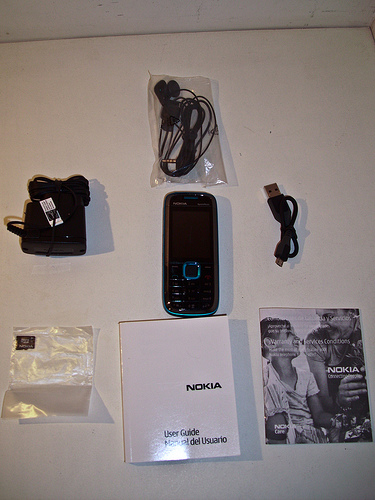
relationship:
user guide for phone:
[117, 315, 242, 465] [160, 190, 220, 316]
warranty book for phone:
[258, 308, 372, 446] [160, 190, 220, 316]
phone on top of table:
[160, 190, 220, 316] [0, 25, 373, 495]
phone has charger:
[160, 190, 220, 316] [8, 175, 92, 257]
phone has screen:
[160, 190, 220, 316] [171, 208, 212, 262]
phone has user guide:
[160, 190, 220, 316] [117, 315, 242, 465]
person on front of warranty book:
[260, 316, 321, 444] [258, 308, 372, 446]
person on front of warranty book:
[305, 308, 370, 442] [258, 308, 372, 446]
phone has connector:
[160, 190, 220, 316] [264, 182, 300, 268]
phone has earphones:
[160, 190, 220, 316] [153, 78, 217, 177]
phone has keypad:
[160, 190, 220, 316] [167, 262, 215, 311]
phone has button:
[160, 190, 220, 316] [183, 262, 199, 279]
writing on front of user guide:
[164, 427, 228, 450] [117, 315, 242, 465]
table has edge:
[0, 25, 373, 495] [1, 22, 374, 47]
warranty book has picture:
[258, 308, 372, 446] [260, 307, 374, 445]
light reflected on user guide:
[151, 433, 189, 462] [117, 315, 242, 465]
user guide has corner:
[117, 315, 242, 465] [121, 445, 140, 472]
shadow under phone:
[214, 194, 234, 315] [160, 190, 220, 316]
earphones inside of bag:
[153, 78, 217, 177] [147, 71, 229, 190]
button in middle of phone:
[183, 262, 199, 279] [160, 190, 220, 316]